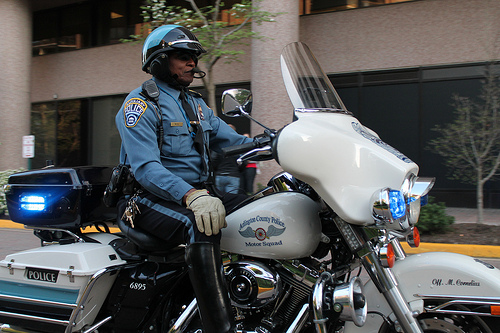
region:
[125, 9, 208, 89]
man wearing a helmet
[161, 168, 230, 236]
man wearing gloves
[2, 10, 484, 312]
a police officer on a bike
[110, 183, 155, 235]
keys connected to the pants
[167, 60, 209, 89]
microphone at the officers mouth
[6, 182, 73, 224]
a bright blue light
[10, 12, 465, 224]
building on the left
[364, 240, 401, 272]
orange right signal light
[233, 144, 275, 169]
brake handle is silver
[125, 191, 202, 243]
light blue stripe on the side of pants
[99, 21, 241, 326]
A police officer.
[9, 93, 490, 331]
A white police motorcycle.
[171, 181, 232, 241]
A gray glove.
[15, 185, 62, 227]
A blue police light.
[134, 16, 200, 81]
A black and blue police helmet.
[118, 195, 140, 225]
Keys on a key chain.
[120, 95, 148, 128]
A police uniform patch.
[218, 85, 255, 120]
A silver motorcycle mirror.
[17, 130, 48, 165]
A white street sign.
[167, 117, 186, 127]
A gold name tag.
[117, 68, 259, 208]
the shirt is blue in color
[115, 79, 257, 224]
the policeman is wearing a long sleeve shirt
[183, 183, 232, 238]
the policeman is wearing gloves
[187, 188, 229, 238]
the glove is white in color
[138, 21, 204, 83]
the policeman is wearing a helmet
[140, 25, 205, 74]
the helmet is blue and black in color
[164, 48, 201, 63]
the policeman is wearing sunglasses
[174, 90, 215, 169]
the policeman is wearing a tie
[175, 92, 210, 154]
the tie is black in color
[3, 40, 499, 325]
the motorcycle is painted white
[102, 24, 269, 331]
a seated police officer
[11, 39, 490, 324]
a white motorcycle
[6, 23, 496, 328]
a police officer riding a motorcycle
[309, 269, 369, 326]
a chrome speaker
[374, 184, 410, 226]
a blue police light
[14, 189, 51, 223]
a blue police light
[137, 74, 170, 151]
a black police radio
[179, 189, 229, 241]
a grey leather driving glove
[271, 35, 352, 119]
a motorcycle windshield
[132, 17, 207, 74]
a blue and black motorcycle helmet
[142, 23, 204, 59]
The helmet the cop is wearing.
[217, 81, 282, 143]
The side view mirror on the motorcycle.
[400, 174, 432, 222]
The front headlight on the motorcycle.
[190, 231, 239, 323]
The black boot the cop is wearing.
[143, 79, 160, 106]
The walkie talkie on the cop's left shoulder.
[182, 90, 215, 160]
The black tie the cop is wearing.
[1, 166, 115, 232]
The back black case with the light on the motorcycle.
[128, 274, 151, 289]
The numbers 6895 on the motorcycle.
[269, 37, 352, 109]
The wind shield on the front of the motorcycle.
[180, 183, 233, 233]
The glove on the cop's hand.